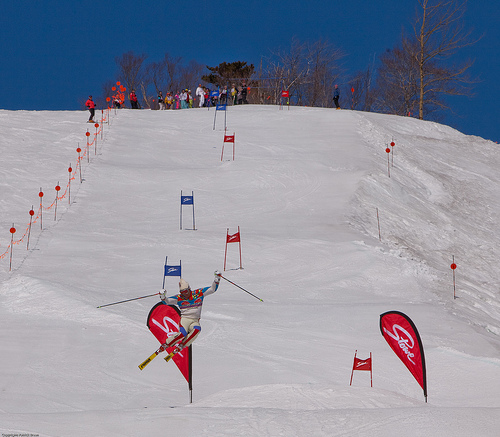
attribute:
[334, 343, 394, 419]
flag — sticking, here, red, black, advertising, obstacle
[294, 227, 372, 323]
snow — here, white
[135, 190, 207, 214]
marker — here, red, blue, sticking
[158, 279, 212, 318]
person — wearing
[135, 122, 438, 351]
hillside — snowy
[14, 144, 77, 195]
line — boundary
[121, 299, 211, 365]
skier — airborn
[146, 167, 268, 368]
slope — ski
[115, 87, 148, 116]
coat — red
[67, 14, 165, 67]
sky — blue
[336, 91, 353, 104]
person — standing, atop, here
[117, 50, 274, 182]
hill — here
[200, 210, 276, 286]
obstacle — flag, blue, here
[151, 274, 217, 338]
uniform — blue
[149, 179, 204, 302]
flags — blue